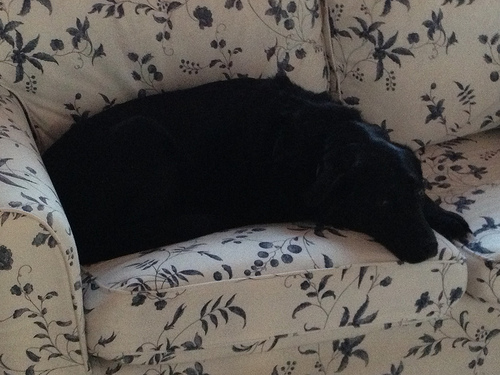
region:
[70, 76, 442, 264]
A black dog laying on a couch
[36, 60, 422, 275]
a black dog sleeping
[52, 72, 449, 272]
a dog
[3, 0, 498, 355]
A white couch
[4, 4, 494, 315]
A blue floral pattern on the couch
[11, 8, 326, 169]
A back cushion for the couch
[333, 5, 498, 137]
the center back cushion for the couch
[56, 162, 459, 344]
A cushioned seat for the couch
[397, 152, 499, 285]
A cushioned seat for the couch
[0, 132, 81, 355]
the armrest of the couch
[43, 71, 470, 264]
A black dog lying on a couch.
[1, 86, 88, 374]
The arm of a couch.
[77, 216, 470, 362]
A cushion a dog is lying on.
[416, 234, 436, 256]
Black nose of a black dog.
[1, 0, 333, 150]
Top cushion above a dog.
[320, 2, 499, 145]
A top cushion to the upper right of a dogs head.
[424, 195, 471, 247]
A black paw of a lying down dog.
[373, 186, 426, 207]
Eyes on a black dogs face.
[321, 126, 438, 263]
Black head of a dog.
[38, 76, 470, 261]
A black dog laying on a couch.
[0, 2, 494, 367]
One dog lying on a couch.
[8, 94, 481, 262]
The dog is black.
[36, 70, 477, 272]
Dog is lying down.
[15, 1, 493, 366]
Couch is white with flowers.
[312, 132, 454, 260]
The dog's face.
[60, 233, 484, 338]
Couch cushion on the left.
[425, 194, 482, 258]
One paw sticking out.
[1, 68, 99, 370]
The arm of the couch.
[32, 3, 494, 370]
Nobody with the dog.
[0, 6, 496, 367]
Photo taken during the day.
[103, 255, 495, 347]
The couch is white and blue.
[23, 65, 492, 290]
The dog is on the couch.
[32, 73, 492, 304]
The dog is sleeping on the couch.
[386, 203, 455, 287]
His snout is long.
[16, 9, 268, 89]
The couch has leaves on it.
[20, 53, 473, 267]
His fur is black.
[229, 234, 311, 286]
Many circles are on the couch.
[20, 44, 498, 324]
The dog is laying on the couch.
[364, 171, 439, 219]
His eyes are black.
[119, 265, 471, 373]
The couch has leaves on it.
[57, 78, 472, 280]
The dog is laying.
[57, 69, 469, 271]
The dog is sleeping.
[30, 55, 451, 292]
The dog is furry.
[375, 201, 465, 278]
The dog's snout is long.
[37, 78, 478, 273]
The dog is sleeping.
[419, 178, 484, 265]
His paw is out.